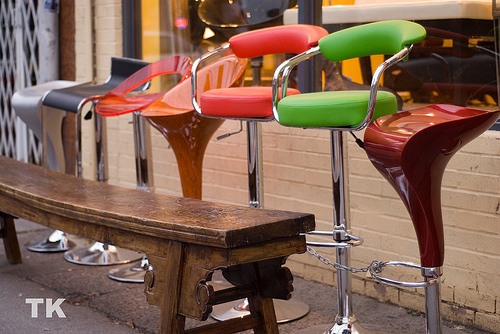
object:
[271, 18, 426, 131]
chair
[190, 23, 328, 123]
chair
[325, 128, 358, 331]
post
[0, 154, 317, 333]
bench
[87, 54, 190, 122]
chair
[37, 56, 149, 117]
chair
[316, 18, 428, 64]
back cushion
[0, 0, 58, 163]
gate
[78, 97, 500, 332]
wall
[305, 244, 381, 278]
chain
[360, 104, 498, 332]
stool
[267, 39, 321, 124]
arm rests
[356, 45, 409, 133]
arm rests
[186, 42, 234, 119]
arm rest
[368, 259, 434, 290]
foot rest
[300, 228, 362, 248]
foot rest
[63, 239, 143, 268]
base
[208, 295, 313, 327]
base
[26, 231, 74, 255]
base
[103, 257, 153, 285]
base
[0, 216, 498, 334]
sidewalk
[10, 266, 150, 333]
lines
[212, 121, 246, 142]
adjustment lever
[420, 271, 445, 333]
pole